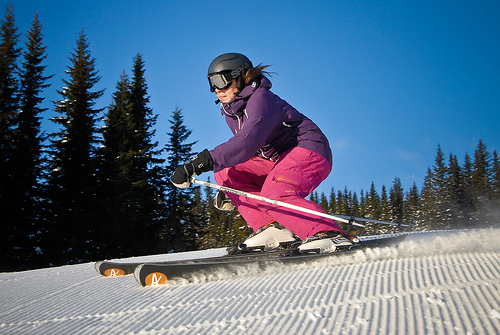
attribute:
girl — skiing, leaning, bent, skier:
[172, 51, 355, 251]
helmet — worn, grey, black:
[208, 52, 251, 90]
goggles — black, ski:
[209, 68, 237, 91]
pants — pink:
[215, 144, 348, 241]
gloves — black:
[170, 147, 215, 185]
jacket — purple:
[209, 77, 334, 166]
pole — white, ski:
[172, 170, 367, 228]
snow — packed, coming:
[2, 226, 498, 334]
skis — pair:
[100, 231, 409, 289]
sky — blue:
[1, 0, 499, 204]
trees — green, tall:
[2, 2, 201, 272]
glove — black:
[168, 147, 217, 184]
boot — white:
[244, 224, 297, 250]